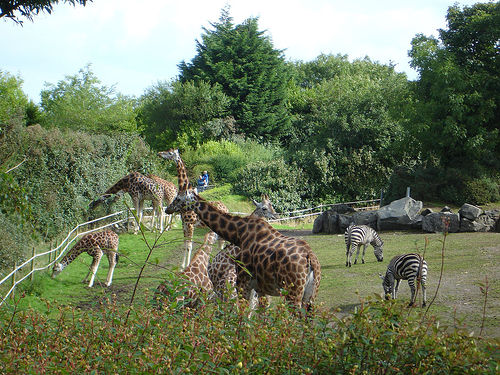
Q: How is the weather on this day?
A: It is partly cloudy.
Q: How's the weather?
A: It is partly cloudy.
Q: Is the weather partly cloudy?
A: Yes, it is partly cloudy.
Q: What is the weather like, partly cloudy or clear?
A: It is partly cloudy.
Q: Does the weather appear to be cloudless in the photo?
A: No, it is partly cloudy.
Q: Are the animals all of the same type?
A: No, there are both giraffes and zebras.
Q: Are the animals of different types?
A: Yes, they are giraffes and zebras.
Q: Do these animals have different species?
A: Yes, they are giraffes and zebras.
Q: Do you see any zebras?
A: Yes, there is a zebra.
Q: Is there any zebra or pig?
A: Yes, there is a zebra.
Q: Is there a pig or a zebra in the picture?
A: Yes, there is a zebra.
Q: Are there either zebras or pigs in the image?
A: Yes, there is a zebra.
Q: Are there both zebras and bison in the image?
A: No, there is a zebra but no bison.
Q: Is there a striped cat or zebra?
A: Yes, there is a striped zebra.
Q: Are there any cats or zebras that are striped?
A: Yes, the zebra is striped.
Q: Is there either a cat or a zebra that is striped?
A: Yes, the zebra is striped.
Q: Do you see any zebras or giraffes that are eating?
A: Yes, the zebra is eating.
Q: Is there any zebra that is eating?
A: Yes, there is a zebra that is eating.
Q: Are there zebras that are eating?
A: Yes, there is a zebra that is eating.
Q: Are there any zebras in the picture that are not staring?
A: Yes, there is a zebra that is eating.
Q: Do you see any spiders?
A: No, there are no spiders.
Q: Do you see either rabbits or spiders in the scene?
A: No, there are no spiders or rabbits.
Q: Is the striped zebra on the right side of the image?
A: Yes, the zebra is on the right of the image.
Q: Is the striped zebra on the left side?
A: No, the zebra is on the right of the image.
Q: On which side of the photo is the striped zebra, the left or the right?
A: The zebra is on the right of the image.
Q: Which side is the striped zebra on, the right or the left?
A: The zebra is on the right of the image.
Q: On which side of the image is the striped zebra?
A: The zebra is on the right of the image.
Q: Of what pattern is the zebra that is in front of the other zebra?
A: The zebra is striped.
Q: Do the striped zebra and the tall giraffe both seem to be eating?
A: Yes, both the zebra and the giraffe are eating.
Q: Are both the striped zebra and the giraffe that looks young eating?
A: Yes, both the zebra and the giraffe are eating.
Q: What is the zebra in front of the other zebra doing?
A: The zebra is eating.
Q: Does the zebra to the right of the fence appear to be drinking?
A: No, the zebra is eating.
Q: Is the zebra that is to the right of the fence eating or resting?
A: The zebra is eating.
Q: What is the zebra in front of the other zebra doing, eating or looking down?
A: The zebra is eating.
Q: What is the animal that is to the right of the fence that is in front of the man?
A: The animal is a zebra.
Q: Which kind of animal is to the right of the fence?
A: The animal is a zebra.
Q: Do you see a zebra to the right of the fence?
A: Yes, there is a zebra to the right of the fence.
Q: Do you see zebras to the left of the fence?
A: No, the zebra is to the right of the fence.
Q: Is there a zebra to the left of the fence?
A: No, the zebra is to the right of the fence.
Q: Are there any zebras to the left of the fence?
A: No, the zebra is to the right of the fence.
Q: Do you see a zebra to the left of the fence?
A: No, the zebra is to the right of the fence.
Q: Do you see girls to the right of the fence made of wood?
A: No, there is a zebra to the right of the fence.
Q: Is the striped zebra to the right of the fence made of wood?
A: Yes, the zebra is to the right of the fence.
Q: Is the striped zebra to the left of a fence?
A: No, the zebra is to the right of a fence.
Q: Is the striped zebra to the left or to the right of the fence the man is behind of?
A: The zebra is to the right of the fence.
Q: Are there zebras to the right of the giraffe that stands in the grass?
A: Yes, there is a zebra to the right of the giraffe.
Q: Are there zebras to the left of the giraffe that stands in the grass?
A: No, the zebra is to the right of the giraffe.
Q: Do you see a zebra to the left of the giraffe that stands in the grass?
A: No, the zebra is to the right of the giraffe.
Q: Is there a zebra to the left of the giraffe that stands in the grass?
A: No, the zebra is to the right of the giraffe.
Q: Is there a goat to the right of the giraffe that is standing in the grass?
A: No, there is a zebra to the right of the giraffe.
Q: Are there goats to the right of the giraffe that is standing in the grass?
A: No, there is a zebra to the right of the giraffe.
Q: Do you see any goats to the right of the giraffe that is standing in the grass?
A: No, there is a zebra to the right of the giraffe.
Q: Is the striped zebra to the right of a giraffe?
A: Yes, the zebra is to the right of a giraffe.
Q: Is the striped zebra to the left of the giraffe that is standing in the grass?
A: No, the zebra is to the right of the giraffe.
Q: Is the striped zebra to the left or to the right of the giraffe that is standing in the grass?
A: The zebra is to the right of the giraffe.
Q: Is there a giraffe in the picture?
A: Yes, there is a giraffe.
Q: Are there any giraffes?
A: Yes, there is a giraffe.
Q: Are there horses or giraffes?
A: Yes, there is a giraffe.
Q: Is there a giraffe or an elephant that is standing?
A: Yes, the giraffe is standing.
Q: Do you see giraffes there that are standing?
A: Yes, there is a giraffe that is standing.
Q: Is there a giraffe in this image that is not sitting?
A: Yes, there is a giraffe that is standing.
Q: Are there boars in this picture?
A: No, there are no boars.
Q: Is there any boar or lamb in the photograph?
A: No, there are no boars or lambs.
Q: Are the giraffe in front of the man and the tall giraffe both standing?
A: Yes, both the giraffe and the giraffe are standing.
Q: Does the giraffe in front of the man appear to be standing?
A: Yes, the giraffe is standing.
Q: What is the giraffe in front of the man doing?
A: The giraffe is standing.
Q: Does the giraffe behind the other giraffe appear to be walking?
A: No, the giraffe is standing.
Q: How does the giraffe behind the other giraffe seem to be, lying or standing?
A: The giraffe is standing.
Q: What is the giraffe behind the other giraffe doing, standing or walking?
A: The giraffe is standing.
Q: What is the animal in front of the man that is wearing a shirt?
A: The animal is a giraffe.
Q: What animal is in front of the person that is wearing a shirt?
A: The animal is a giraffe.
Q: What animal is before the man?
A: The animal is a giraffe.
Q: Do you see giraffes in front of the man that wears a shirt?
A: Yes, there is a giraffe in front of the man.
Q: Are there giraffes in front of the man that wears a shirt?
A: Yes, there is a giraffe in front of the man.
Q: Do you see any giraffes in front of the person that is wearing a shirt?
A: Yes, there is a giraffe in front of the man.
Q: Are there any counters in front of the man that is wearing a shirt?
A: No, there is a giraffe in front of the man.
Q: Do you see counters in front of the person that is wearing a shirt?
A: No, there is a giraffe in front of the man.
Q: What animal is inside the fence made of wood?
A: The giraffe is inside the fence.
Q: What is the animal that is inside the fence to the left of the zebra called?
A: The animal is a giraffe.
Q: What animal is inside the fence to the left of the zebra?
A: The animal is a giraffe.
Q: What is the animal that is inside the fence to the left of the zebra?
A: The animal is a giraffe.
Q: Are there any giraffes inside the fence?
A: Yes, there is a giraffe inside the fence.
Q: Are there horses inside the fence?
A: No, there is a giraffe inside the fence.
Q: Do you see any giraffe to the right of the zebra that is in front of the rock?
A: No, the giraffe is to the left of the zebra.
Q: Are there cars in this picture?
A: No, there are no cars.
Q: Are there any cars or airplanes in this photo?
A: No, there are no cars or airplanes.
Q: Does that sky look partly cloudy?
A: Yes, the sky is partly cloudy.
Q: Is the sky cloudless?
A: No, the sky is partly cloudy.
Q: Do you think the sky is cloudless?
A: No, the sky is partly cloudy.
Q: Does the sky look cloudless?
A: No, the sky is partly cloudy.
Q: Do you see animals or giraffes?
A: Yes, there is a giraffe.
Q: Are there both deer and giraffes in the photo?
A: No, there is a giraffe but no deer.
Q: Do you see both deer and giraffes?
A: No, there is a giraffe but no deer.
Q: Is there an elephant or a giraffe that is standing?
A: Yes, the giraffe is standing.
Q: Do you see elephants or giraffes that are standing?
A: Yes, the giraffe is standing.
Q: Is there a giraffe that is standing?
A: Yes, there is a giraffe that is standing.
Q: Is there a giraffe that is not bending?
A: Yes, there is a giraffe that is standing.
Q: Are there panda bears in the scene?
A: No, there are no panda bears.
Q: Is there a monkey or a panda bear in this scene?
A: No, there are no pandas or monkeys.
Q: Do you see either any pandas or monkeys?
A: No, there are no pandas or monkeys.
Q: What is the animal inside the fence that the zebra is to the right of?
A: The animal is a giraffe.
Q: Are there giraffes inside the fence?
A: Yes, there is a giraffe inside the fence.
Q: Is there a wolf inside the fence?
A: No, there is a giraffe inside the fence.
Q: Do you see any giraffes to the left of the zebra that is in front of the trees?
A: Yes, there is a giraffe to the left of the zebra.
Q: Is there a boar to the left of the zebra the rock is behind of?
A: No, there is a giraffe to the left of the zebra.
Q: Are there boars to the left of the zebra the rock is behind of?
A: No, there is a giraffe to the left of the zebra.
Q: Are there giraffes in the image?
A: Yes, there is a giraffe.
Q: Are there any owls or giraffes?
A: Yes, there is a giraffe.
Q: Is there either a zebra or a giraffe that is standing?
A: Yes, the giraffe is standing.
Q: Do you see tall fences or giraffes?
A: Yes, there is a tall giraffe.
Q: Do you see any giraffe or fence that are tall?
A: Yes, the giraffe is tall.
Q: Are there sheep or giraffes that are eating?
A: Yes, the giraffe is eating.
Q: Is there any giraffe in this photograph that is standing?
A: Yes, there is a giraffe that is standing.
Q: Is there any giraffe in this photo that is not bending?
A: Yes, there is a giraffe that is standing.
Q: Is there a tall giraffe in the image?
A: Yes, there is a tall giraffe.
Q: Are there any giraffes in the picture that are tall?
A: Yes, there is a giraffe that is tall.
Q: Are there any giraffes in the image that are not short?
A: Yes, there is a tall giraffe.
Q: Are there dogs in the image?
A: No, there are no dogs.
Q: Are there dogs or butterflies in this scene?
A: No, there are no dogs or butterflies.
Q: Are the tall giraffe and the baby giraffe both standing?
A: Yes, both the giraffe and the giraffe are standing.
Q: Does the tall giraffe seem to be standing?
A: Yes, the giraffe is standing.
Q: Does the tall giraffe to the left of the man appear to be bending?
A: No, the giraffe is standing.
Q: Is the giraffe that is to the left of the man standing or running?
A: The giraffe is standing.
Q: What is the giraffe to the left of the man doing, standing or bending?
A: The giraffe is standing.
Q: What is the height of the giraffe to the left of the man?
A: The giraffe is tall.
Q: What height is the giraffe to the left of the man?
A: The giraffe is tall.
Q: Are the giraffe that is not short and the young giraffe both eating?
A: Yes, both the giraffe and the giraffe are eating.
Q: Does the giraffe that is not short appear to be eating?
A: Yes, the giraffe is eating.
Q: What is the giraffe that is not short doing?
A: The giraffe is eating.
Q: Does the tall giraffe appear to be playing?
A: No, the giraffe is eating.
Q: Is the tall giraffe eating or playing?
A: The giraffe is eating.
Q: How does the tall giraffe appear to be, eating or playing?
A: The giraffe is eating.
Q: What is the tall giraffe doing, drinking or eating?
A: The giraffe is eating.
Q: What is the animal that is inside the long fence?
A: The animal is a giraffe.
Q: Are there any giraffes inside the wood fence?
A: Yes, there is a giraffe inside the fence.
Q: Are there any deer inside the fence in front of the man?
A: No, there is a giraffe inside the fence.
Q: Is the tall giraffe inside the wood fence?
A: Yes, the giraffe is inside the fence.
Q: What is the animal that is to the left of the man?
A: The animal is a giraffe.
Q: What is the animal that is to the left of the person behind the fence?
A: The animal is a giraffe.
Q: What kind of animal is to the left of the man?
A: The animal is a giraffe.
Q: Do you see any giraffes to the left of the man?
A: Yes, there is a giraffe to the left of the man.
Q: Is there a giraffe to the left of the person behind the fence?
A: Yes, there is a giraffe to the left of the man.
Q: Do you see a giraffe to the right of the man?
A: No, the giraffe is to the left of the man.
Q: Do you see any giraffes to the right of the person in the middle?
A: No, the giraffe is to the left of the man.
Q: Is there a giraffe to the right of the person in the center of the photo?
A: No, the giraffe is to the left of the man.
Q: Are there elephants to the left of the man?
A: No, there is a giraffe to the left of the man.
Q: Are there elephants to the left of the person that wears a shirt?
A: No, there is a giraffe to the left of the man.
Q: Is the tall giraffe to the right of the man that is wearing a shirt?
A: No, the giraffe is to the left of the man.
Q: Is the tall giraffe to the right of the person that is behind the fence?
A: No, the giraffe is to the left of the man.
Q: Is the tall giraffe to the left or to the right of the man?
A: The giraffe is to the left of the man.